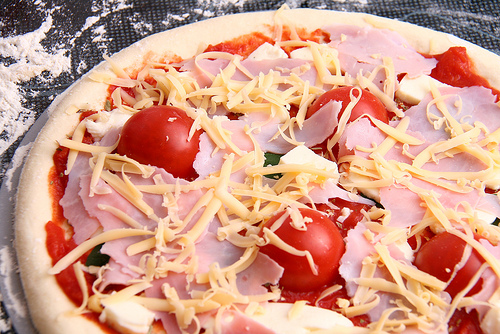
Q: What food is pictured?
A: Pizza.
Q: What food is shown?
A: Pizza.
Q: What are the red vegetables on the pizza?
A: Tomatoes.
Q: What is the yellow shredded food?
A: Cheese.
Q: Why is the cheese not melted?
A: Pizza isn't cooked.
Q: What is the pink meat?
A: Ham.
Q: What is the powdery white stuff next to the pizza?
A: Flour.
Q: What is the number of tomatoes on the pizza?
A: 4.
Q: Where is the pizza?
A: On counter.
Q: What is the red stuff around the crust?
A: Sauce.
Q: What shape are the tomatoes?
A: Round.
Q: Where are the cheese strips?
A: On the pizza.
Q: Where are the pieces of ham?
A: On the pizza.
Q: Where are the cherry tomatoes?
A: On the pizza.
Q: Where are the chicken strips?
A: On the pizza.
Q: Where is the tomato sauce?
A: On the pizza.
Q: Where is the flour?
A: On the table.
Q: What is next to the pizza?
A: Flour.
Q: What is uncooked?
A: The pizza.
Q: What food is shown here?
A: Pizza.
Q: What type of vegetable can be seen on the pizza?
A: Tomatoes.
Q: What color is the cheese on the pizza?
A: Yellow.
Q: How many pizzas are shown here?
A: One.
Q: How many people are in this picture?
A: Zero.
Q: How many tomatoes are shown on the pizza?
A: Four.